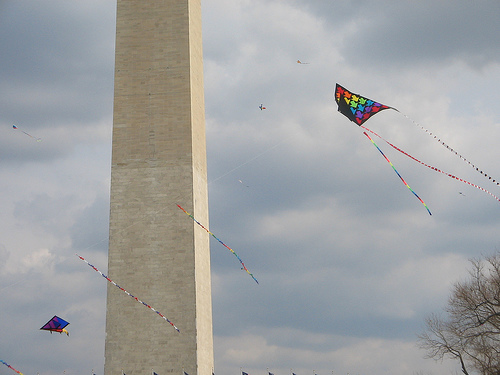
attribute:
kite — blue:
[176, 204, 259, 284]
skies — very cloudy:
[6, 7, 476, 290]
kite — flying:
[318, 65, 477, 211]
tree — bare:
[408, 257, 496, 351]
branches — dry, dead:
[414, 248, 499, 373]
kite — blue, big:
[37, 304, 82, 339]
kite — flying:
[324, 72, 437, 234]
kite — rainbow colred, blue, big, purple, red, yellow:
[327, 82, 499, 220]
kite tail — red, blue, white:
[361, 124, 496, 207]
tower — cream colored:
[109, 0, 201, 370]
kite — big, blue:
[37, 313, 72, 340]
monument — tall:
[105, 2, 214, 373]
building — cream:
[101, 0, 217, 370]